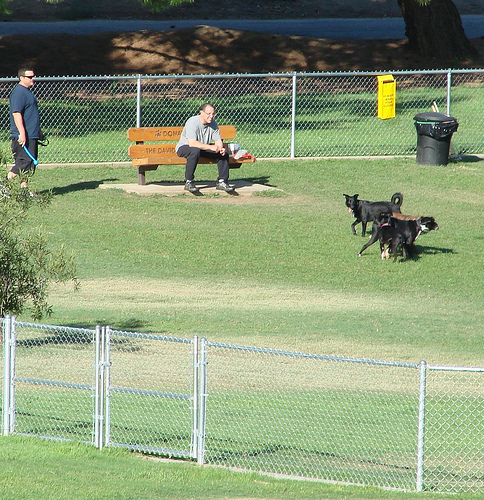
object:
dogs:
[357, 215, 440, 257]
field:
[0, 130, 483, 499]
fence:
[0, 317, 483, 490]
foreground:
[5, 227, 473, 499]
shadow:
[58, 69, 469, 139]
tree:
[395, 0, 465, 75]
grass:
[0, 428, 483, 499]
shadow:
[20, 401, 483, 492]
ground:
[0, 146, 484, 499]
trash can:
[412, 110, 458, 166]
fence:
[0, 66, 483, 166]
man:
[176, 102, 236, 192]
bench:
[127, 125, 258, 188]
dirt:
[115, 178, 271, 196]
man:
[5, 67, 50, 198]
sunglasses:
[23, 73, 39, 83]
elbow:
[188, 137, 195, 148]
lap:
[177, 147, 195, 159]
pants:
[175, 144, 230, 182]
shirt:
[174, 114, 223, 153]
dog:
[377, 212, 407, 264]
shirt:
[8, 83, 41, 138]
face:
[24, 71, 34, 86]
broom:
[431, 100, 465, 162]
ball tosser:
[18, 146, 39, 165]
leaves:
[24, 212, 37, 232]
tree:
[0, 144, 81, 328]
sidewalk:
[1, 0, 484, 70]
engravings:
[154, 129, 182, 137]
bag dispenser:
[377, 74, 396, 120]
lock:
[98, 358, 115, 371]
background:
[0, 0, 483, 232]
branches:
[2, 287, 14, 306]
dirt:
[45, 23, 380, 76]